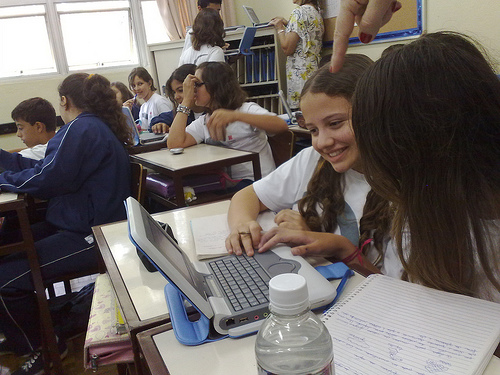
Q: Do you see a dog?
A: No, there are no dogs.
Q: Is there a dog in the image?
A: No, there are no dogs.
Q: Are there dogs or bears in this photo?
A: No, there are no dogs or bears.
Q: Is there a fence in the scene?
A: No, there are no fences.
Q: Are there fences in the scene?
A: No, there are no fences.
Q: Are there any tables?
A: Yes, there is a table.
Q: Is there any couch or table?
A: Yes, there is a table.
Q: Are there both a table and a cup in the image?
A: No, there is a table but no cups.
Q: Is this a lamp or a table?
A: This is a table.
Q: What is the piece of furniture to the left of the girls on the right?
A: The piece of furniture is a table.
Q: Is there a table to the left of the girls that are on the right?
A: Yes, there is a table to the left of the girls.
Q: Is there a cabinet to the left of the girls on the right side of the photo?
A: No, there is a table to the left of the girls.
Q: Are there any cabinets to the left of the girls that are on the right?
A: No, there is a table to the left of the girls.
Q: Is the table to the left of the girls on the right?
A: Yes, the table is to the left of the girls.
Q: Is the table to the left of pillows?
A: No, the table is to the left of the girls.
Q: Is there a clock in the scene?
A: No, there are no clocks.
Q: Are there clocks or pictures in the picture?
A: No, there are no clocks or pictures.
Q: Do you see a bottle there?
A: Yes, there is a bottle.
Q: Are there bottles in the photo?
A: Yes, there is a bottle.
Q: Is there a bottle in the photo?
A: Yes, there is a bottle.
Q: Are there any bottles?
A: Yes, there is a bottle.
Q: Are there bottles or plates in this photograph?
A: Yes, there is a bottle.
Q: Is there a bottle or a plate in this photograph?
A: Yes, there is a bottle.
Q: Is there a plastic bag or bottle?
A: Yes, there is a plastic bottle.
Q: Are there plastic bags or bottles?
A: Yes, there is a plastic bottle.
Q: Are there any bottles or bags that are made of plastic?
A: Yes, the bottle is made of plastic.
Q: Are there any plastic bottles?
A: Yes, there is a bottle that is made of plastic.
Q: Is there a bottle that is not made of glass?
A: Yes, there is a bottle that is made of plastic.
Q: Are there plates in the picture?
A: No, there are no plates.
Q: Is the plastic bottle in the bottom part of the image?
A: Yes, the bottle is in the bottom of the image.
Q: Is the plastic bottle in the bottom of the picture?
A: Yes, the bottle is in the bottom of the image.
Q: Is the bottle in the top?
A: No, the bottle is in the bottom of the image.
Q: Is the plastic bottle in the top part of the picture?
A: No, the bottle is in the bottom of the image.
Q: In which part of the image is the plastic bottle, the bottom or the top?
A: The bottle is in the bottom of the image.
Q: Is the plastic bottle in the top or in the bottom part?
A: The bottle is in the bottom of the image.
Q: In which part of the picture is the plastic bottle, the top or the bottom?
A: The bottle is in the bottom of the image.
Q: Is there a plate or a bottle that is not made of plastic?
A: No, there is a bottle but it is made of plastic.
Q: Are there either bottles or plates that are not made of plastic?
A: No, there is a bottle but it is made of plastic.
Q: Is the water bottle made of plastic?
A: Yes, the bottle is made of plastic.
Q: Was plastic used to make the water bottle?
A: Yes, the bottle is made of plastic.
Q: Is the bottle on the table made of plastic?
A: Yes, the bottle is made of plastic.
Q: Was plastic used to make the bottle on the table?
A: Yes, the bottle is made of plastic.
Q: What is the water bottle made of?
A: The bottle is made of plastic.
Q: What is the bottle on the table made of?
A: The bottle is made of plastic.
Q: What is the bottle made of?
A: The bottle is made of plastic.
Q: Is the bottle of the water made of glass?
A: No, the bottle is made of plastic.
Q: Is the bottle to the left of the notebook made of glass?
A: No, the bottle is made of plastic.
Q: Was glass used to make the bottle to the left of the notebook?
A: No, the bottle is made of plastic.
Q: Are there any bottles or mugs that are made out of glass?
A: No, there is a bottle but it is made of plastic.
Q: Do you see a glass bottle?
A: No, there is a bottle but it is made of plastic.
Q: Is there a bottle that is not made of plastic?
A: No, there is a bottle but it is made of plastic.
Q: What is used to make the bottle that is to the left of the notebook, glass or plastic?
A: The bottle is made of plastic.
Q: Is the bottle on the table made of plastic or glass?
A: The bottle is made of plastic.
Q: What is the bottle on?
A: The bottle is on the table.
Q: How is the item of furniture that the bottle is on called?
A: The piece of furniture is a table.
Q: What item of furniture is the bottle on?
A: The bottle is on the table.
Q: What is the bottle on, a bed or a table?
A: The bottle is on a table.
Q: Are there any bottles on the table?
A: Yes, there is a bottle on the table.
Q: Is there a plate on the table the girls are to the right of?
A: No, there is a bottle on the table.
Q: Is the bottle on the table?
A: Yes, the bottle is on the table.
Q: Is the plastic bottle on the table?
A: Yes, the bottle is on the table.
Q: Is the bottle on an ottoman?
A: No, the bottle is on the table.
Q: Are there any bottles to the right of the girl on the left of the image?
A: Yes, there is a bottle to the right of the girl.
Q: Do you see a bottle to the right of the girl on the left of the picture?
A: Yes, there is a bottle to the right of the girl.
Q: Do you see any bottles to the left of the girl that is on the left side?
A: No, the bottle is to the right of the girl.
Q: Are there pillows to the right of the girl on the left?
A: No, there is a bottle to the right of the girl.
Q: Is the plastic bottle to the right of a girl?
A: Yes, the bottle is to the right of a girl.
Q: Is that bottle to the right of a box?
A: No, the bottle is to the right of a girl.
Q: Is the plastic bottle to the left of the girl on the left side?
A: No, the bottle is to the right of the girl.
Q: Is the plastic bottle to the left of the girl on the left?
A: No, the bottle is to the right of the girl.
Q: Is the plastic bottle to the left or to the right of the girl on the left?
A: The bottle is to the right of the girl.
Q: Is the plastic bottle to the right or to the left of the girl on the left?
A: The bottle is to the right of the girl.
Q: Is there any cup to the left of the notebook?
A: No, there is a bottle to the left of the notebook.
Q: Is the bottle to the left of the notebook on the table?
A: Yes, the bottle is to the left of the notebook.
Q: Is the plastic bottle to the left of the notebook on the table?
A: Yes, the bottle is to the left of the notebook.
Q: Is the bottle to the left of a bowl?
A: No, the bottle is to the left of the notebook.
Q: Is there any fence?
A: No, there are no fences.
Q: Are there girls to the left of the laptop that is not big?
A: Yes, there is a girl to the left of the laptop computer.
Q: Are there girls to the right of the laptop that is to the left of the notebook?
A: No, the girl is to the left of the laptop computer.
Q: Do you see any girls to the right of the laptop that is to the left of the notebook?
A: No, the girl is to the left of the laptop computer.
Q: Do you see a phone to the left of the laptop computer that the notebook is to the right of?
A: No, there is a girl to the left of the laptop.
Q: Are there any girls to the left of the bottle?
A: Yes, there is a girl to the left of the bottle.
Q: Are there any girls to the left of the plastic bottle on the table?
A: Yes, there is a girl to the left of the bottle.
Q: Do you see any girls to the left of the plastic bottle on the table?
A: Yes, there is a girl to the left of the bottle.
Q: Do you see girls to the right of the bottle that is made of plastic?
A: No, the girl is to the left of the bottle.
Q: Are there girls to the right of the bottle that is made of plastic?
A: No, the girl is to the left of the bottle.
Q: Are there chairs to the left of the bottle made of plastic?
A: No, there is a girl to the left of the bottle.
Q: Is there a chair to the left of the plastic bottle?
A: No, there is a girl to the left of the bottle.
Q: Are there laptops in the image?
A: Yes, there is a laptop.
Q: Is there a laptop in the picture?
A: Yes, there is a laptop.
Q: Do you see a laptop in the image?
A: Yes, there is a laptop.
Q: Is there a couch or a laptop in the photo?
A: Yes, there is a laptop.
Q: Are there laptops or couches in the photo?
A: Yes, there is a laptop.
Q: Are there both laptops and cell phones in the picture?
A: No, there is a laptop but no cell phones.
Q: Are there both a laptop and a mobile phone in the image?
A: No, there is a laptop but no cell phones.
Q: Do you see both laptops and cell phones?
A: No, there is a laptop but no cell phones.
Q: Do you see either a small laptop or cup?
A: Yes, there is a small laptop.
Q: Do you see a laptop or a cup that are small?
A: Yes, the laptop is small.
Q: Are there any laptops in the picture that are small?
A: Yes, there is a small laptop.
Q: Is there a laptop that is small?
A: Yes, there is a laptop that is small.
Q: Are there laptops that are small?
A: Yes, there is a laptop that is small.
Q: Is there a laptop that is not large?
A: Yes, there is a small laptop.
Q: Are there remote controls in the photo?
A: No, there are no remote controls.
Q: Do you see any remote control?
A: No, there are no remote controls.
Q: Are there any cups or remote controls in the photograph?
A: No, there are no remote controls or cups.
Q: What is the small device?
A: The device is a laptop.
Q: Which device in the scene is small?
A: The device is a laptop.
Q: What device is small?
A: The device is a laptop.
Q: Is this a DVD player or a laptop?
A: This is a laptop.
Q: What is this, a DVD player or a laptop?
A: This is a laptop.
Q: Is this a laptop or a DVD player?
A: This is a laptop.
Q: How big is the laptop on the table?
A: The laptop is small.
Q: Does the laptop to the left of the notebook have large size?
A: No, the laptop is small.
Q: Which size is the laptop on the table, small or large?
A: The laptop is small.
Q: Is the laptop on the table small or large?
A: The laptop is small.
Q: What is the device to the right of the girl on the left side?
A: The device is a laptop.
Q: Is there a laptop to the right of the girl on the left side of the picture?
A: Yes, there is a laptop to the right of the girl.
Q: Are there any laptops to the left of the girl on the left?
A: No, the laptop is to the right of the girl.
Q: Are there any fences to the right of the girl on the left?
A: No, there is a laptop to the right of the girl.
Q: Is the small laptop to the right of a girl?
A: Yes, the laptop computer is to the right of a girl.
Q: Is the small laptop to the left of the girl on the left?
A: No, the laptop is to the right of the girl.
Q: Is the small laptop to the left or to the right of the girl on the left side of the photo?
A: The laptop is to the right of the girl.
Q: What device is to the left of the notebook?
A: The device is a laptop.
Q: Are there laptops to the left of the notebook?
A: Yes, there is a laptop to the left of the notebook.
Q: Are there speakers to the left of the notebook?
A: No, there is a laptop to the left of the notebook.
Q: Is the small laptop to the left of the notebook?
A: Yes, the laptop computer is to the left of the notebook.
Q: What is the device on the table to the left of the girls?
A: The device is a laptop.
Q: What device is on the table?
A: The device is a laptop.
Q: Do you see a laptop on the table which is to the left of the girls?
A: Yes, there is a laptop on the table.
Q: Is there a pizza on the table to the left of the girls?
A: No, there is a laptop on the table.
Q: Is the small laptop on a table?
A: Yes, the laptop is on a table.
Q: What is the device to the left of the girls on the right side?
A: The device is a laptop.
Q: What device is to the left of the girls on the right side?
A: The device is a laptop.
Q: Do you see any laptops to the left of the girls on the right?
A: Yes, there is a laptop to the left of the girls.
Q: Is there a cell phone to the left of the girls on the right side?
A: No, there is a laptop to the left of the girls.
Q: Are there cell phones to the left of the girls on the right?
A: No, there is a laptop to the left of the girls.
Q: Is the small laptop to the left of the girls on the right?
A: Yes, the laptop is to the left of the girls.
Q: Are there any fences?
A: No, there are no fences.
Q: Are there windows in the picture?
A: Yes, there are windows.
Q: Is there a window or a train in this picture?
A: Yes, there are windows.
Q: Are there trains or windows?
A: Yes, there are windows.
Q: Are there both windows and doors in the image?
A: No, there are windows but no doors.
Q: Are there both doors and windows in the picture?
A: No, there are windows but no doors.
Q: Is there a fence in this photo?
A: No, there are no fences.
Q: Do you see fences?
A: No, there are no fences.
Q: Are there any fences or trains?
A: No, there are no fences or trains.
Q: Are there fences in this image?
A: No, there are no fences.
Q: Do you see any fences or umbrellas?
A: No, there are no fences or umbrellas.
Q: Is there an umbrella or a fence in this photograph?
A: No, there are no fences or umbrellas.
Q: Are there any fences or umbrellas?
A: No, there are no fences or umbrellas.